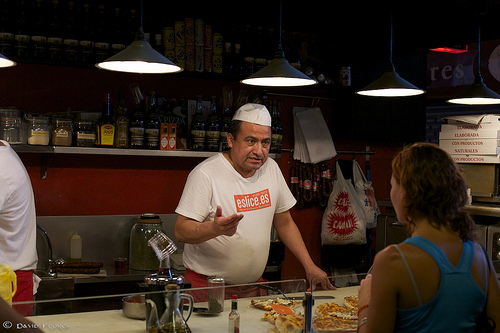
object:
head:
[226, 102, 273, 171]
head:
[387, 140, 469, 228]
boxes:
[449, 154, 500, 164]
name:
[12, 321, 54, 333]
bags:
[320, 160, 368, 246]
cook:
[171, 100, 339, 303]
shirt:
[173, 150, 299, 288]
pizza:
[249, 294, 366, 333]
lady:
[362, 138, 500, 332]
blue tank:
[393, 235, 491, 333]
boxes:
[438, 127, 499, 140]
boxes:
[438, 146, 500, 156]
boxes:
[440, 124, 500, 132]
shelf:
[376, 197, 500, 219]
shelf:
[8, 142, 283, 160]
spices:
[95, 114, 116, 147]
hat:
[230, 102, 272, 128]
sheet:
[292, 106, 339, 165]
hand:
[210, 205, 245, 237]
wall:
[0, 66, 410, 272]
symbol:
[233, 188, 272, 214]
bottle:
[143, 281, 196, 333]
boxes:
[447, 115, 498, 124]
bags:
[352, 159, 382, 229]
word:
[236, 193, 270, 209]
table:
[21, 283, 361, 333]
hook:
[280, 148, 376, 164]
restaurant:
[0, 0, 500, 333]